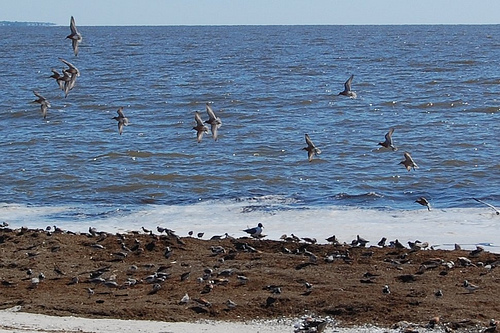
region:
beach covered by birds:
[0, 221, 497, 332]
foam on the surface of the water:
[3, 193, 498, 254]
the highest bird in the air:
[63, 14, 88, 57]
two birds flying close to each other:
[189, 104, 225, 144]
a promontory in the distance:
[2, 18, 57, 28]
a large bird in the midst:
[242, 218, 265, 239]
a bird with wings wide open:
[64, 13, 81, 54]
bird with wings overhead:
[334, 69, 361, 99]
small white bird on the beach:
[140, 225, 152, 235]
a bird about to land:
[413, 194, 434, 212]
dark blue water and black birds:
[310, 38, 393, 109]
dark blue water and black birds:
[244, 76, 345, 152]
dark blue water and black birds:
[64, 126, 124, 163]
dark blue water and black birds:
[364, 99, 474, 132]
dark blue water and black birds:
[303, 113, 356, 145]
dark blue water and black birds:
[60, 78, 147, 129]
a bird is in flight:
[64, 17, 82, 56]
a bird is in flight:
[110, 106, 132, 136]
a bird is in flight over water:
[338, 73, 361, 102]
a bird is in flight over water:
[301, 134, 322, 161]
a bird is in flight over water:
[412, 191, 432, 211]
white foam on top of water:
[3, 189, 498, 254]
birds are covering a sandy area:
[0, 215, 498, 332]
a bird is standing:
[241, 221, 265, 239]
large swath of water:
[1, 24, 498, 246]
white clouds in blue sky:
[331, 18, 410, 36]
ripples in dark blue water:
[200, 45, 278, 75]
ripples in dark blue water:
[405, 64, 450, 94]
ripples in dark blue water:
[447, 90, 466, 103]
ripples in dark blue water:
[96, 164, 137, 194]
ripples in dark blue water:
[12, 156, 61, 190]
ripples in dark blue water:
[130, 160, 175, 193]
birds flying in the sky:
[323, 81, 422, 176]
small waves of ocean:
[194, 28, 499, 80]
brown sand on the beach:
[176, 255, 380, 331]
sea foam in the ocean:
[181, 197, 496, 250]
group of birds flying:
[6, 44, 111, 115]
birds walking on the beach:
[187, 222, 397, 287]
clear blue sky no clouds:
[165, 2, 471, 25]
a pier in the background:
[2, 18, 59, 32]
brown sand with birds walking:
[299, 267, 467, 320]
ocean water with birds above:
[39, 132, 254, 203]